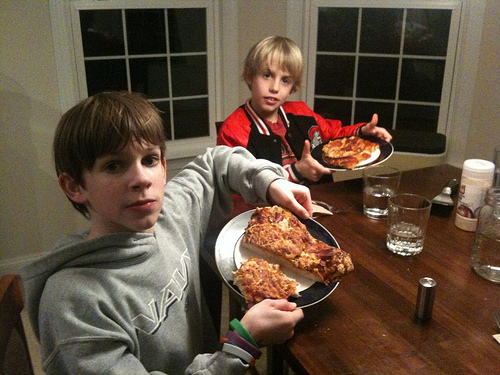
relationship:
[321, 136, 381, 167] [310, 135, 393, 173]
pizza on a plate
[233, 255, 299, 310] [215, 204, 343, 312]
chicken on a plate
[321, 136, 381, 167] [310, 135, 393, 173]
pizza sitting on a plate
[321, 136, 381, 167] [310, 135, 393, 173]
pizza resting on a plate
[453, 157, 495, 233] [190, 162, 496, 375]
can sitting on table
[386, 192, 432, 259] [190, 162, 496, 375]
glass sitting on table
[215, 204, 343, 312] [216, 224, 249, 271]
plate has a reflection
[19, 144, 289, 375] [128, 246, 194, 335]
sweatshirt has a logo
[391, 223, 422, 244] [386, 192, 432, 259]
liquid in glass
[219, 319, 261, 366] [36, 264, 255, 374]
bands are on arm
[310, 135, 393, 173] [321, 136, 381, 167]
plate holding pizza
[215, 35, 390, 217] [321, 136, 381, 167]
boy holding pizza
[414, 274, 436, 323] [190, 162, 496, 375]
salt sitting on table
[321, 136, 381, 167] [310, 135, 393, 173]
pizza sitting on plate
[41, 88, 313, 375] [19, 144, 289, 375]
boy has a sweatshirt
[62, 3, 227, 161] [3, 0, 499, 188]
window in background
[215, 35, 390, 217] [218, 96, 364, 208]
boy wearing a jacket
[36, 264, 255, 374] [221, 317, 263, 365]
arm has bands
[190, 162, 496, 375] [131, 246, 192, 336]
table has logo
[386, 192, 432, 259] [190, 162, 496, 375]
glass on table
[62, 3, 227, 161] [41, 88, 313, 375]
window behind boy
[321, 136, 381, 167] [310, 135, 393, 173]
pizza on plate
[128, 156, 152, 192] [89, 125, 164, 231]
nose on face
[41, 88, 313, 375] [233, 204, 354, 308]
boy holding pizza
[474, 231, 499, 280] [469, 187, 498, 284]
water in a jar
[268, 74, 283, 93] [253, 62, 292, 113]
nose on a face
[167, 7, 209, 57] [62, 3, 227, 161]
pane in a window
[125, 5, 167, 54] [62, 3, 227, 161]
pane in a window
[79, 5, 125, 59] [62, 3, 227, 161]
pane in a window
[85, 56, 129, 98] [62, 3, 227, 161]
pane in a window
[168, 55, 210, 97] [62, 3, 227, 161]
pane in a window